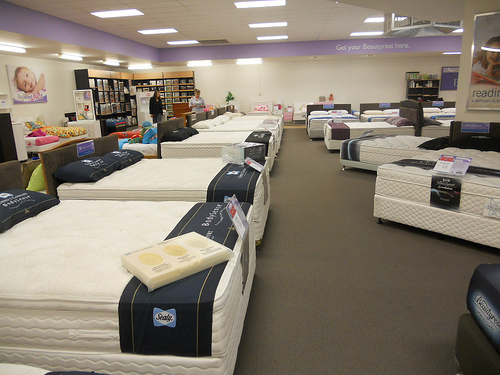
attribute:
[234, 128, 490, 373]
carpet — gray , commercial 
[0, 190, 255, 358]
mattress — attached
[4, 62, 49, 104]
picture — hanging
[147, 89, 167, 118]
dark shirt — dark 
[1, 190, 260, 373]
mattresses — white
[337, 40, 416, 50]
lettering — white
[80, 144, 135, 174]
pillows. — blue , for sale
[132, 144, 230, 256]
mattresses — white 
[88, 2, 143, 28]
light — flourescent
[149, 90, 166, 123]
woman — walking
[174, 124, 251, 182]
pillows — multi-colored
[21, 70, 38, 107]
face — baby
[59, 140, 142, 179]
headboard — rectangular , dark 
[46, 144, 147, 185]
pillows — rectangular , black 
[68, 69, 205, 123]
display — black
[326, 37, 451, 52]
border — purple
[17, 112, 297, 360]
sheets — attached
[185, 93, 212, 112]
shirt — light colored